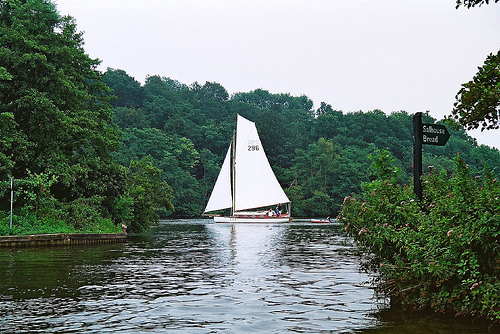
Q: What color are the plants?
A: Green.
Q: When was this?
A: Daytime.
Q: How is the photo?
A: Clear.